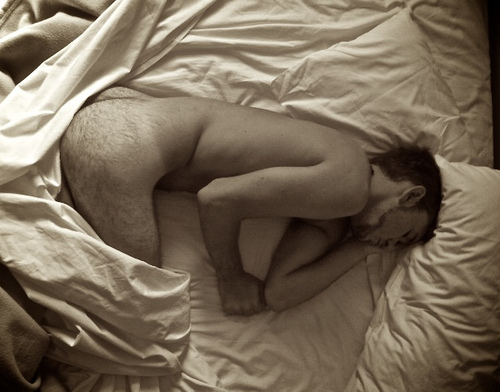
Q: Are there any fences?
A: No, there are no fences.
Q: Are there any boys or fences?
A: No, there are no fences or boys.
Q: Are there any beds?
A: Yes, there is a bed.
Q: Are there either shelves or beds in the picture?
A: Yes, there is a bed.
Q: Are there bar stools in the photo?
A: No, there are no bar stools.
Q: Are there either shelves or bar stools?
A: No, there are no bar stools or shelves.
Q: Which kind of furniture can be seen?
A: The furniture is a bed.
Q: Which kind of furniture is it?
A: The piece of furniture is a bed.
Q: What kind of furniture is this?
A: This is a bed.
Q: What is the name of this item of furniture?
A: This is a bed.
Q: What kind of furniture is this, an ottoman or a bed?
A: This is a bed.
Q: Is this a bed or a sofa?
A: This is a bed.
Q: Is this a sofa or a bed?
A: This is a bed.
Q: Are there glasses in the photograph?
A: No, there are no glasses.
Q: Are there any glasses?
A: No, there are no glasses.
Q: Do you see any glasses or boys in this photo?
A: No, there are no glasses or boys.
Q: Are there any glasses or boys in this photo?
A: No, there are no glasses or boys.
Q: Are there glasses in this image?
A: No, there are no glasses.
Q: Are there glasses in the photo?
A: No, there are no glasses.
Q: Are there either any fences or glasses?
A: No, there are no glasses or fences.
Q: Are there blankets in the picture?
A: Yes, there is a blanket.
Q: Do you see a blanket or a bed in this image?
A: Yes, there is a blanket.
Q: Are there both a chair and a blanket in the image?
A: No, there is a blanket but no chairs.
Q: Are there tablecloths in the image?
A: No, there are no tablecloths.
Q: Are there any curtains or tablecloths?
A: No, there are no tablecloths or curtains.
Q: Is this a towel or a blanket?
A: This is a blanket.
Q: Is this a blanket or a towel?
A: This is a blanket.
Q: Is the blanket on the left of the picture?
A: Yes, the blanket is on the left of the image.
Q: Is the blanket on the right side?
A: No, the blanket is on the left of the image.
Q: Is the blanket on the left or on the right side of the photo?
A: The blanket is on the left of the image.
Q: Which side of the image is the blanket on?
A: The blanket is on the left of the image.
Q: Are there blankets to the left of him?
A: Yes, there is a blanket to the left of the man.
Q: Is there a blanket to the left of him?
A: Yes, there is a blanket to the left of the man.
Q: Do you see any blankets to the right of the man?
A: No, the blanket is to the left of the man.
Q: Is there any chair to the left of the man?
A: No, there is a blanket to the left of the man.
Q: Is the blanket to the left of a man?
A: Yes, the blanket is to the left of a man.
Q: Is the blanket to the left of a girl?
A: No, the blanket is to the left of a man.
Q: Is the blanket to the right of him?
A: No, the blanket is to the left of a man.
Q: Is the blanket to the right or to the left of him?
A: The blanket is to the left of the man.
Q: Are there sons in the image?
A: No, there are no sons.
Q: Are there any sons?
A: No, there are no sons.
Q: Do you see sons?
A: No, there are no sons.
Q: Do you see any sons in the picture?
A: No, there are no sons.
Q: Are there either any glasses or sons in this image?
A: No, there are no sons or glasses.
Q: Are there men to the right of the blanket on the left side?
A: Yes, there is a man to the right of the blanket.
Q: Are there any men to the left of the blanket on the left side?
A: No, the man is to the right of the blanket.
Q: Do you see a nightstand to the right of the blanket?
A: No, there is a man to the right of the blanket.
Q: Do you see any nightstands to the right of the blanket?
A: No, there is a man to the right of the blanket.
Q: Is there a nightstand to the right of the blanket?
A: No, there is a man to the right of the blanket.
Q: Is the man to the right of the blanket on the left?
A: Yes, the man is to the right of the blanket.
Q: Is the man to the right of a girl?
A: No, the man is to the right of the blanket.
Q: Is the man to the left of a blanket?
A: No, the man is to the right of a blanket.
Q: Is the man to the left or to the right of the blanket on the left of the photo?
A: The man is to the right of the blanket.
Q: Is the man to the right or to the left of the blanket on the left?
A: The man is to the right of the blanket.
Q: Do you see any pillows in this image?
A: Yes, there is a pillow.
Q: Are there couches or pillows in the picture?
A: Yes, there is a pillow.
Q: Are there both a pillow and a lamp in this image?
A: No, there is a pillow but no lamps.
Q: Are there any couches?
A: No, there are no couches.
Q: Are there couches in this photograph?
A: No, there are no couches.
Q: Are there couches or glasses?
A: No, there are no couches or glasses.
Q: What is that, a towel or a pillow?
A: That is a pillow.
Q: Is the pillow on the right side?
A: Yes, the pillow is on the right of the image.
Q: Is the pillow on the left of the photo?
A: No, the pillow is on the right of the image.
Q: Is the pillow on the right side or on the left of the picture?
A: The pillow is on the right of the image.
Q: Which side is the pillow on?
A: The pillow is on the right of the image.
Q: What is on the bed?
A: The pillow is on the bed.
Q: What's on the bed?
A: The pillow is on the bed.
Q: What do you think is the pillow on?
A: The pillow is on the bed.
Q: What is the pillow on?
A: The pillow is on the bed.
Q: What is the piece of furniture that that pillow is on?
A: The piece of furniture is a bed.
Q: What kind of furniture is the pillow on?
A: The pillow is on the bed.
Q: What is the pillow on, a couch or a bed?
A: The pillow is on a bed.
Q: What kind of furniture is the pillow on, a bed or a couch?
A: The pillow is on a bed.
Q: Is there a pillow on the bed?
A: Yes, there is a pillow on the bed.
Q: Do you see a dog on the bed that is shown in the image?
A: No, there is a pillow on the bed.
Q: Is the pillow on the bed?
A: Yes, the pillow is on the bed.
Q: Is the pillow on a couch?
A: No, the pillow is on the bed.